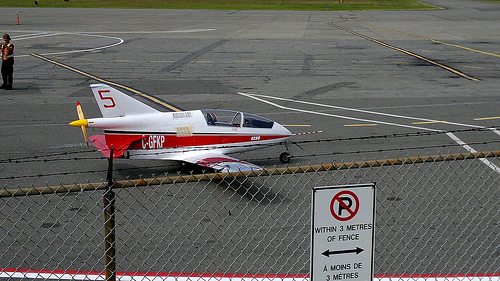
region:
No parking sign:
[312, 187, 371, 279]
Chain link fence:
[1, 177, 450, 279]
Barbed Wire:
[2, 128, 496, 185]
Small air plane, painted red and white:
[57, 67, 302, 177]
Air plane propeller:
[58, 96, 93, 149]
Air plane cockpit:
[195, 100, 285, 135]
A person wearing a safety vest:
[0, 28, 26, 96]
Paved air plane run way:
[1, 1, 497, 271]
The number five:
[86, 78, 126, 108]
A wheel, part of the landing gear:
[269, 145, 296, 170]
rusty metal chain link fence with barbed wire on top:
[0, 134, 498, 278]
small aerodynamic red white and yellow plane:
[67, 80, 290, 178]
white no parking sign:
[310, 182, 377, 280]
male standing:
[0, 32, 15, 84]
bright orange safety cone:
[12, 11, 21, 28]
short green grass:
[2, 0, 444, 12]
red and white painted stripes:
[1, 271, 496, 277]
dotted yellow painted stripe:
[257, 110, 497, 137]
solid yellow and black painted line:
[27, 47, 187, 117]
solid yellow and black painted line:
[330, 9, 492, 85]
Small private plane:
[67, 71, 299, 181]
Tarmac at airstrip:
[331, 30, 496, 130]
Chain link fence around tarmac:
[391, 147, 493, 263]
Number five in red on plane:
[93, 81, 118, 108]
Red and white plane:
[65, 71, 305, 183]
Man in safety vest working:
[0, 30, 16, 93]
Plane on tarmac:
[37, 63, 492, 180]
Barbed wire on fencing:
[395, 117, 491, 263]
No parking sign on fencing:
[295, 140, 394, 280]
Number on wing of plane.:
[85, 85, 127, 115]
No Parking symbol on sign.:
[327, 192, 367, 222]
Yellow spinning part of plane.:
[65, 103, 85, 144]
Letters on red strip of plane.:
[132, 130, 172, 153]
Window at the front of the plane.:
[198, 107, 279, 129]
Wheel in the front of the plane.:
[275, 143, 299, 163]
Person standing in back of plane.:
[2, 26, 30, 101]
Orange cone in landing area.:
[8, 3, 32, 31]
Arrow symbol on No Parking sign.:
[321, 244, 376, 259]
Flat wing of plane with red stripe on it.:
[172, 155, 262, 180]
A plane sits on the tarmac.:
[55, 59, 342, 211]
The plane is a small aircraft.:
[60, 80, 302, 202]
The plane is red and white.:
[63, 70, 308, 201]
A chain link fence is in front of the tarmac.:
[0, 153, 498, 279]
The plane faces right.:
[54, 73, 310, 201]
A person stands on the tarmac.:
[0, 25, 19, 95]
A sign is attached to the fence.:
[295, 177, 394, 279]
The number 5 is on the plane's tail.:
[93, 84, 125, 114]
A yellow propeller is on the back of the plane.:
[61, 95, 92, 147]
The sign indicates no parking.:
[327, 187, 368, 235]